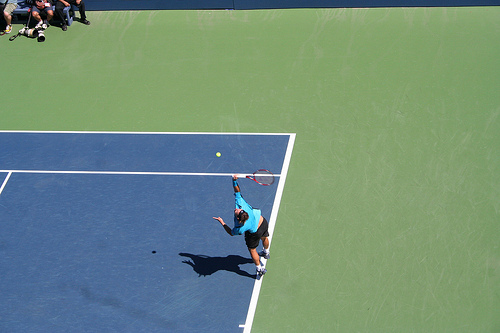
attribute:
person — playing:
[214, 175, 272, 277]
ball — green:
[215, 151, 222, 160]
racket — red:
[234, 168, 274, 189]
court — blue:
[2, 132, 290, 333]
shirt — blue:
[232, 195, 262, 235]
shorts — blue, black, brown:
[245, 217, 270, 249]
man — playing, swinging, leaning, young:
[215, 177, 271, 279]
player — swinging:
[214, 174, 269, 280]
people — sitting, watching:
[1, 0, 88, 31]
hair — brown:
[237, 211, 249, 224]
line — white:
[3, 130, 296, 139]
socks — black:
[256, 262, 263, 273]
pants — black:
[246, 216, 269, 252]